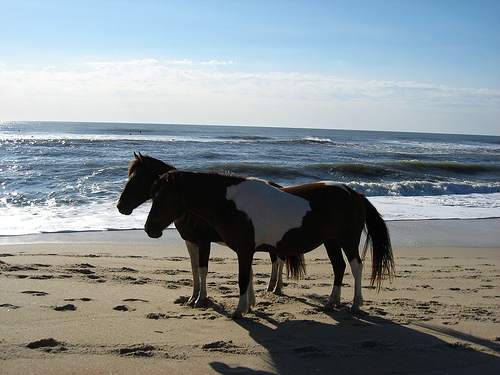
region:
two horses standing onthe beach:
[104, 116, 406, 330]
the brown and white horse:
[160, 165, 361, 292]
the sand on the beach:
[46, 251, 132, 361]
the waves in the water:
[19, 136, 46, 202]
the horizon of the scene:
[73, 118, 206, 149]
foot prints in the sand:
[422, 268, 455, 353]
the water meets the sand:
[417, 205, 462, 250]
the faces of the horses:
[120, 151, 177, 235]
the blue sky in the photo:
[181, 24, 316, 65]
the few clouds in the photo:
[77, 48, 229, 98]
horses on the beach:
[32, 65, 439, 336]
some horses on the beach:
[56, 72, 446, 345]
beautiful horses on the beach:
[50, 83, 442, 350]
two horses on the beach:
[52, 79, 457, 344]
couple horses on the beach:
[22, 83, 457, 334]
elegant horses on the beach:
[49, 97, 449, 339]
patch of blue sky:
[36, 28, 434, 113]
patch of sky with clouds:
[56, 33, 450, 120]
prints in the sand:
[17, 291, 290, 361]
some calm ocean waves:
[40, 127, 477, 154]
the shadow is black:
[265, 317, 443, 374]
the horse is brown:
[164, 170, 376, 275]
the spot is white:
[225, 180, 310, 247]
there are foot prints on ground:
[103, 305, 183, 366]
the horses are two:
[106, 161, 398, 315]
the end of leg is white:
[352, 263, 372, 311]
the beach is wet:
[425, 214, 497, 251]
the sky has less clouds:
[150, 73, 350, 118]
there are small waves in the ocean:
[326, 130, 456, 181]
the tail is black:
[369, 226, 421, 277]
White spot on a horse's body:
[223, 178, 316, 251]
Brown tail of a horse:
[363, 197, 397, 288]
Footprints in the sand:
[23, 331, 478, 368]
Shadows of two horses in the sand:
[245, 321, 465, 373]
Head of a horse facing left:
[113, 148, 155, 223]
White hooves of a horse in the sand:
[187, 264, 207, 311]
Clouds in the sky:
[35, 60, 203, 103]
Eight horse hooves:
[167, 258, 387, 323]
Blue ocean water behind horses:
[15, 140, 115, 195]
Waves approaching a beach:
[345, 160, 495, 220]